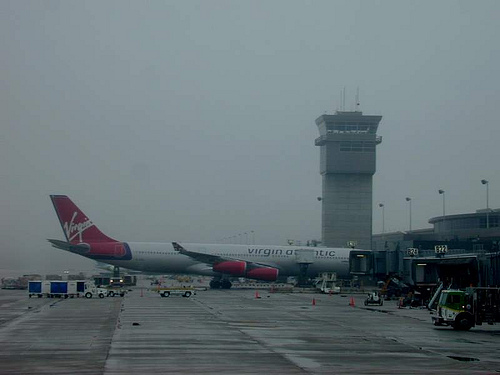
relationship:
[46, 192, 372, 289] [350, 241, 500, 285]
plane parked at terminal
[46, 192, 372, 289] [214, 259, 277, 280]
plane has engine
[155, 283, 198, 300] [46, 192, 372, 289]
vehicle next to plane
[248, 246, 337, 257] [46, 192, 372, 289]
sign on plane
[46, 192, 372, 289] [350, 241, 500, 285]
plane at terminal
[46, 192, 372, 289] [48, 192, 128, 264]
plane has tail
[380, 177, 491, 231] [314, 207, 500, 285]
lights on building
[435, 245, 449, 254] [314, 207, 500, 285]
numbers on building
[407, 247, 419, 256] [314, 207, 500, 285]
numbers on building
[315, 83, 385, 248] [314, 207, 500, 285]
tower at building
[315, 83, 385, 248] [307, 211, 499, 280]
tower at airport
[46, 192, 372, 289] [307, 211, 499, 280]
plane at airport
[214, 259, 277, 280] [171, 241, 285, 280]
engine on wing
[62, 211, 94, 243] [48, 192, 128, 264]
lettering on tail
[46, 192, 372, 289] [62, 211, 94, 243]
plane has lettering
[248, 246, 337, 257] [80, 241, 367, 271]
lettering on side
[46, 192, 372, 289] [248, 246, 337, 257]
plane has lettering